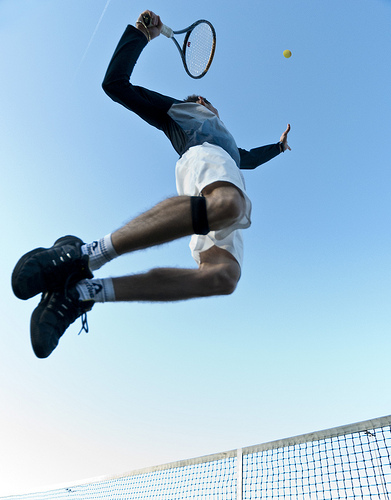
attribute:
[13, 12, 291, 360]
player — tennis, jumping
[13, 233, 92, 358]
sneakers — tennis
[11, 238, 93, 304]
sneaker — player's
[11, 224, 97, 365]
feet — player's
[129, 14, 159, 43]
wrist — player's